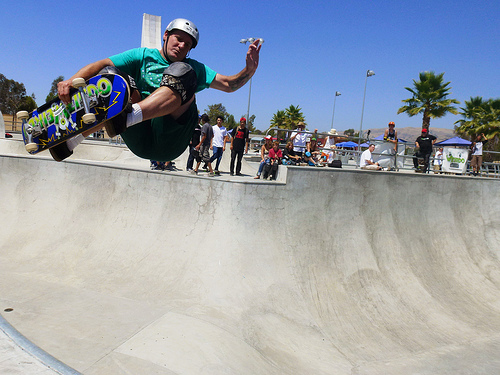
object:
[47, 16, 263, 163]
man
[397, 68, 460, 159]
tree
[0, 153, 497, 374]
pool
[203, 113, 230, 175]
person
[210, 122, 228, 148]
t-shirt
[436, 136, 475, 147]
umbrella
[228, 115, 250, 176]
man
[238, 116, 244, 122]
hat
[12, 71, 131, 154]
skateboard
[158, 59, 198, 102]
kneepad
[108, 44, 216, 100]
shirt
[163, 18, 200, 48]
helmet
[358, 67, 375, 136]
lightposts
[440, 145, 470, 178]
sign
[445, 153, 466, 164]
text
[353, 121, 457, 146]
hills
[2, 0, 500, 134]
sky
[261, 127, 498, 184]
fence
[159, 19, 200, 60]
head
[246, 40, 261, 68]
hand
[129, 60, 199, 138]
leg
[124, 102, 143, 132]
sock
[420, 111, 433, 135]
trunk